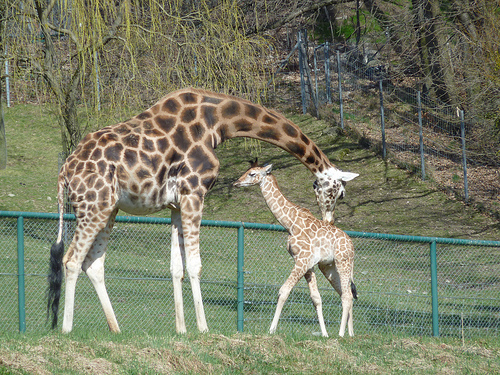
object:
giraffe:
[232, 163, 357, 340]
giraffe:
[55, 85, 358, 336]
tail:
[42, 169, 65, 332]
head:
[231, 164, 273, 192]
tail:
[351, 243, 358, 301]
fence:
[351, 235, 497, 350]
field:
[359, 335, 471, 374]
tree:
[0, 0, 264, 172]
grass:
[303, 362, 325, 374]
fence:
[310, 49, 500, 219]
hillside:
[364, 173, 427, 229]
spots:
[293, 217, 307, 231]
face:
[316, 171, 338, 217]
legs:
[309, 273, 330, 338]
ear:
[341, 170, 361, 183]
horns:
[249, 159, 255, 167]